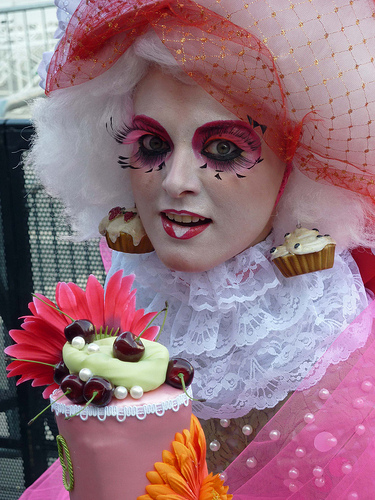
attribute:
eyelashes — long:
[101, 112, 268, 183]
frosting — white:
[265, 225, 306, 268]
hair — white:
[33, 80, 165, 237]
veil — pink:
[241, 415, 335, 480]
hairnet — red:
[50, 3, 371, 189]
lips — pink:
[157, 206, 211, 238]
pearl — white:
[128, 384, 146, 401]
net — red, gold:
[44, 0, 374, 197]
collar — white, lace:
[110, 248, 374, 399]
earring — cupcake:
[85, 200, 160, 260]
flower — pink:
[6, 268, 165, 397]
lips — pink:
[156, 223, 209, 239]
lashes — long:
[113, 116, 169, 165]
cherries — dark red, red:
[6, 290, 205, 425]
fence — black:
[6, 122, 92, 438]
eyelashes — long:
[102, 109, 175, 174]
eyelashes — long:
[122, 118, 274, 181]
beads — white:
[94, 77, 254, 230]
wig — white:
[26, 0, 372, 267]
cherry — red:
[109, 331, 144, 361]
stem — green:
[129, 304, 168, 342]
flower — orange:
[27, 242, 152, 398]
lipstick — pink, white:
[166, 224, 198, 234]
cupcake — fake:
[266, 222, 344, 276]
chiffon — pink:
[278, 408, 352, 493]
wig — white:
[33, 81, 127, 232]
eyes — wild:
[123, 118, 248, 181]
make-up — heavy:
[188, 117, 260, 174]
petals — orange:
[172, 436, 202, 492]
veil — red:
[176, 29, 286, 92]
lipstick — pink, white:
[165, 221, 204, 239]